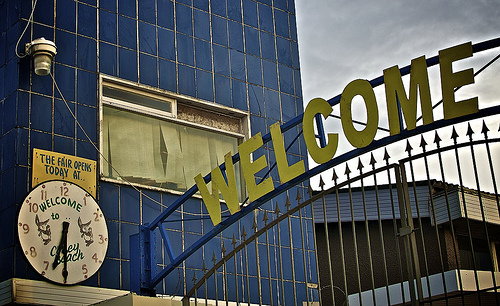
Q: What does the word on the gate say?
A: Welcome.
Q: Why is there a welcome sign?
A: To welcome people.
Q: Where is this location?
A: Park.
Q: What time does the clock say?
A: Six thirty.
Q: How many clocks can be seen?
A: One.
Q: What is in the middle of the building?
A: Window.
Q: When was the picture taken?
A: Daytime.